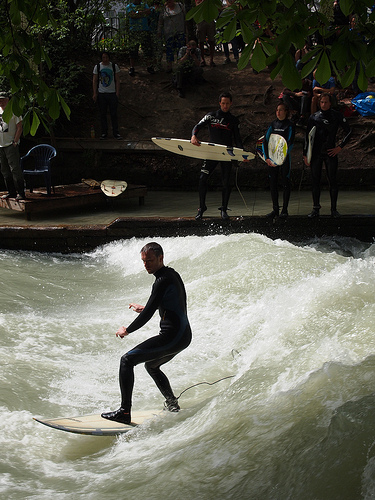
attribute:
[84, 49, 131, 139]
man — standing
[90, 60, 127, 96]
shirt — white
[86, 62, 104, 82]
sleeve — short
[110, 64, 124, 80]
sleeve — short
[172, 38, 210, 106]
man — sitting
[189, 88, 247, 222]
man — standing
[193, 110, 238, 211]
wetsuit — black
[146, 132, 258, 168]
surfboard — white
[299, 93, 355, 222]
man — standing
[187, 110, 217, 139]
sleeve — long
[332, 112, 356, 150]
sleeve — long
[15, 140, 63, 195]
chair — plastic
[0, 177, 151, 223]
platform — wood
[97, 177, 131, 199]
surfboard — white